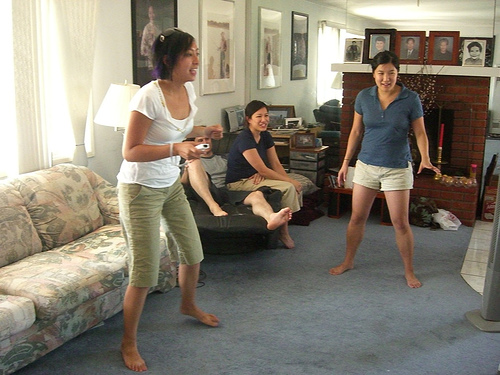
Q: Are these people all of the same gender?
A: Yes, all the people are female.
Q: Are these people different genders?
A: No, all the people are female.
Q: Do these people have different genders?
A: No, all the people are female.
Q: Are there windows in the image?
A: Yes, there is a window.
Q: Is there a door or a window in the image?
A: Yes, there is a window.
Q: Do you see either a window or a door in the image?
A: Yes, there is a window.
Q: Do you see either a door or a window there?
A: Yes, there is a window.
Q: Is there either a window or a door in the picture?
A: Yes, there is a window.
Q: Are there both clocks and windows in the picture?
A: No, there is a window but no clocks.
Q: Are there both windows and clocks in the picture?
A: No, there is a window but no clocks.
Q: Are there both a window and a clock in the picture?
A: No, there is a window but no clocks.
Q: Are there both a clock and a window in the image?
A: No, there is a window but no clocks.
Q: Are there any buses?
A: No, there are no buses.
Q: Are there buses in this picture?
A: No, there are no buses.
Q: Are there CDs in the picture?
A: No, there are no cds.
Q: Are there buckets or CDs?
A: No, there are no CDs or buckets.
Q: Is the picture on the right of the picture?
A: Yes, the picture is on the right of the image.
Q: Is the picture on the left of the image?
A: No, the picture is on the right of the image.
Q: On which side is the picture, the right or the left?
A: The picture is on the right of the image.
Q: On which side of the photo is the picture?
A: The picture is on the right of the image.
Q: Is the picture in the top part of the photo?
A: Yes, the picture is in the top of the image.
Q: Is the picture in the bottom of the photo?
A: No, the picture is in the top of the image.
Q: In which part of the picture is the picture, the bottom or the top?
A: The picture is in the top of the image.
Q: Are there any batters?
A: No, there are no batters.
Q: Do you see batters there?
A: No, there are no batters.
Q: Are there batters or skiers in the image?
A: No, there are no batters or skiers.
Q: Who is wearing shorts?
A: The girl is wearing shorts.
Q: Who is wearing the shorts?
A: The girl is wearing shorts.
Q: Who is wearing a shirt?
A: The girl is wearing a shirt.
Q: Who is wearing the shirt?
A: The girl is wearing a shirt.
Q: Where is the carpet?
A: The carpet is on the floor.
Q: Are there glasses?
A: No, there are no glasses.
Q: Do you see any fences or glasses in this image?
A: No, there are no glasses or fences.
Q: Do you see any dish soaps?
A: No, there are no dish soaps.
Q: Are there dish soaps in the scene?
A: No, there are no dish soaps.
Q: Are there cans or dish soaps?
A: No, there are no dish soaps or cans.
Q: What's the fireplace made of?
A: The fire place is made of brick.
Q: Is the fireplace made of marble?
A: No, the fireplace is made of brick.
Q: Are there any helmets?
A: No, there are no helmets.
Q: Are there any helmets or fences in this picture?
A: No, there are no helmets or fences.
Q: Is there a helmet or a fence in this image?
A: No, there are no helmets or fences.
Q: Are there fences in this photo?
A: No, there are no fences.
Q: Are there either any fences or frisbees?
A: No, there are no fences or frisbees.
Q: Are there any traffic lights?
A: No, there are no traffic lights.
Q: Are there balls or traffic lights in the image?
A: No, there are no traffic lights or balls.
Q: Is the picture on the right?
A: Yes, the picture is on the right of the image.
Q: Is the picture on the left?
A: No, the picture is on the right of the image.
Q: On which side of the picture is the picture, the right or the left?
A: The picture is on the right of the image.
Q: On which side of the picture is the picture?
A: The picture is on the right of the image.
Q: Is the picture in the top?
A: Yes, the picture is in the top of the image.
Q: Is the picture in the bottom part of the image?
A: No, the picture is in the top of the image.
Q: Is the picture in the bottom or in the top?
A: The picture is in the top of the image.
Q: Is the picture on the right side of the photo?
A: Yes, the picture is on the right of the image.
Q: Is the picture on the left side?
A: No, the picture is on the right of the image.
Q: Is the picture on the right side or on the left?
A: The picture is on the right of the image.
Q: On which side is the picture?
A: The picture is on the right of the image.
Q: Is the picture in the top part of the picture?
A: Yes, the picture is in the top of the image.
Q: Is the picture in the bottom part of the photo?
A: No, the picture is in the top of the image.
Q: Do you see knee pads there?
A: No, there are no knee pads.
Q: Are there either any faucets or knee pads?
A: No, there are no knee pads or faucets.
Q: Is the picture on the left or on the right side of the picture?
A: The picture is on the right of the image.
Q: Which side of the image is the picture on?
A: The picture is on the right of the image.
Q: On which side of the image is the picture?
A: The picture is on the right of the image.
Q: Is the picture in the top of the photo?
A: Yes, the picture is in the top of the image.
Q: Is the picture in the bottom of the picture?
A: No, the picture is in the top of the image.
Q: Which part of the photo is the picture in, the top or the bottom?
A: The picture is in the top of the image.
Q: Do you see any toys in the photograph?
A: No, there are no toys.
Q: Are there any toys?
A: No, there are no toys.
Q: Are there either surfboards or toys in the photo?
A: No, there are no toys or surfboards.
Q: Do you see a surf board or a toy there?
A: No, there are no toys or surfboards.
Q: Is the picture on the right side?
A: Yes, the picture is on the right of the image.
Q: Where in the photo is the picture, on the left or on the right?
A: The picture is on the right of the image.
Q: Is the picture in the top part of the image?
A: Yes, the picture is in the top of the image.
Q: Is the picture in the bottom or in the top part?
A: The picture is in the top of the image.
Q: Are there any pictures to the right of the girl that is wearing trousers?
A: Yes, there is a picture to the right of the girl.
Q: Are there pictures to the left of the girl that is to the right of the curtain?
A: No, the picture is to the right of the girl.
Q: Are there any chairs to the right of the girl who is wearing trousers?
A: No, there is a picture to the right of the girl.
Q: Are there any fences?
A: No, there are no fences.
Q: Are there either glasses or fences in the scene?
A: No, there are no fences or glasses.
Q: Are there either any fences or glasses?
A: No, there are no fences or glasses.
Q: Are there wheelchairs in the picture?
A: No, there are no wheelchairs.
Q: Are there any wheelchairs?
A: No, there are no wheelchairs.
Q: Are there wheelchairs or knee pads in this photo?
A: No, there are no wheelchairs or knee pads.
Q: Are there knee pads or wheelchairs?
A: No, there are no wheelchairs or knee pads.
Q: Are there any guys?
A: No, there are no guys.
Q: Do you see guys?
A: No, there are no guys.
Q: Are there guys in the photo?
A: No, there are no guys.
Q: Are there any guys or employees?
A: No, there are no guys or employees.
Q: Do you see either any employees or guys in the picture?
A: No, there are no guys or employees.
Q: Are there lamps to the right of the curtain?
A: No, there is a girl to the right of the curtain.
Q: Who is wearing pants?
A: The girl is wearing pants.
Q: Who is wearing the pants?
A: The girl is wearing pants.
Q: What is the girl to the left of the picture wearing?
A: The girl is wearing pants.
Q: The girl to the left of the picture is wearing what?
A: The girl is wearing pants.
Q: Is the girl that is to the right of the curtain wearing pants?
A: Yes, the girl is wearing pants.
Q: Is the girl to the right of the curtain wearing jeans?
A: No, the girl is wearing pants.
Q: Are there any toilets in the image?
A: No, there are no toilets.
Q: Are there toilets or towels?
A: No, there are no toilets or towels.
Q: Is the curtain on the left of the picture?
A: Yes, the curtain is on the left of the image.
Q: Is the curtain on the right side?
A: No, the curtain is on the left of the image.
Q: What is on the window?
A: The curtain is on the window.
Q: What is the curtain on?
A: The curtain is on the window.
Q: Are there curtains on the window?
A: Yes, there is a curtain on the window.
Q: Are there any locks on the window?
A: No, there is a curtain on the window.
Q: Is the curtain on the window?
A: Yes, the curtain is on the window.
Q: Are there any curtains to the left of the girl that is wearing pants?
A: Yes, there is a curtain to the left of the girl.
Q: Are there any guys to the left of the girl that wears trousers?
A: No, there is a curtain to the left of the girl.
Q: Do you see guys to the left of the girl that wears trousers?
A: No, there is a curtain to the left of the girl.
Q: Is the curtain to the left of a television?
A: No, the curtain is to the left of a girl.